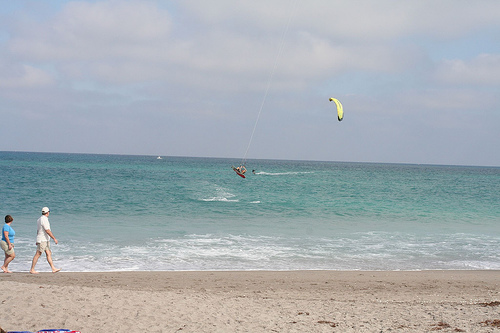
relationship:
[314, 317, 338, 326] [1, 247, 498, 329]
footprints on beach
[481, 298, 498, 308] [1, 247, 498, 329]
footprints on beach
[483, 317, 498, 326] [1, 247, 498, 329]
footprints on beach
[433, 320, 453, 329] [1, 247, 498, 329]
footprints on beach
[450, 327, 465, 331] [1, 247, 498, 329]
footprints on beach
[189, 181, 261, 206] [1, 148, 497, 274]
wave in water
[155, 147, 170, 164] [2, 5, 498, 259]
boat in distance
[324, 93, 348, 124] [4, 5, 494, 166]
kite on sky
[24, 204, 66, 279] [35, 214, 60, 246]
man wearing a shirt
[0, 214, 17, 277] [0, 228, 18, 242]
woman wearing shirt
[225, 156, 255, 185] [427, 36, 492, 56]
surfer in sky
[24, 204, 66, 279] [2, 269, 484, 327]
man walking on beach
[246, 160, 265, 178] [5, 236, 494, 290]
man walking on beach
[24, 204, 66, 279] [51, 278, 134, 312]
man walking on beach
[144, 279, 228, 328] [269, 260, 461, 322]
footprints in sand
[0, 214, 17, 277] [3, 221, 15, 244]
woman wearing shirt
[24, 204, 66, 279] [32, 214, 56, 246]
man wearing shirt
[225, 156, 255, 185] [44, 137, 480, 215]
surfer in ocean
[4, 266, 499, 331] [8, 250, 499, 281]
sand at edge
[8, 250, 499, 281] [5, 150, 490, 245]
edge of water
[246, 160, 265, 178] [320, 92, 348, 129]
man has sail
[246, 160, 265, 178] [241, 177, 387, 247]
man in water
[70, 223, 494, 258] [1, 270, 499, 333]
wave crashing beach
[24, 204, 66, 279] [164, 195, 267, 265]
man walking along water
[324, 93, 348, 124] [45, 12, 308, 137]
kite in sky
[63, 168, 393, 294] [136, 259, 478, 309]
waves coming towards shore line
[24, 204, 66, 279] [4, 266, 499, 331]
man walking on beach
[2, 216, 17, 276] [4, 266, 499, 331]
woman walking on beach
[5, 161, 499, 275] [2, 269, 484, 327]
water meeting beach